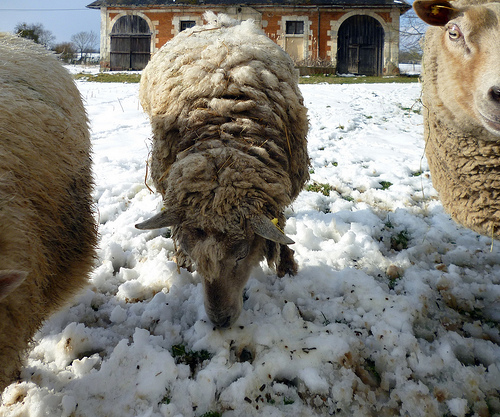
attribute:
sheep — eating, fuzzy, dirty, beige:
[131, 6, 334, 330]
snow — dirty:
[2, 58, 498, 416]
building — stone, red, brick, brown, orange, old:
[89, 0, 407, 84]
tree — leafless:
[68, 30, 106, 73]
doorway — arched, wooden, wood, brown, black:
[330, 6, 400, 83]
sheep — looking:
[415, 2, 499, 254]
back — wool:
[142, 17, 318, 159]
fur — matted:
[163, 72, 306, 189]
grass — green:
[73, 66, 153, 90]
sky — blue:
[1, 2, 499, 71]